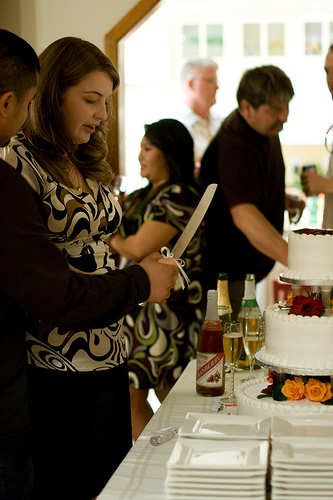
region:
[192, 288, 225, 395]
a bottle of red liquid with white top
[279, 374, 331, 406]
a set of yellow flowers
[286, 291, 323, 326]
a red flower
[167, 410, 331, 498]
stacks of small square plates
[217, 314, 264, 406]
a pair of champagne glasses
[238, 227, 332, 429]
a multi-layered cake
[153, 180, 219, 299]
a large cake knife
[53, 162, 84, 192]
a necklace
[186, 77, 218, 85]
a pair of corrective glasses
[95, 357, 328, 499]
a white tablecloth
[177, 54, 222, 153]
gray haired man in background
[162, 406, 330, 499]
stacks of white plates on table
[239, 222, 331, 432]
three tier white wedding cake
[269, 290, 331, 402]
decorative flowers on wedding cake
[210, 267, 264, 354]
two opened bottles of champagne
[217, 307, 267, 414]
several glasses of champagne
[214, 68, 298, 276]
mustached man in brown shirt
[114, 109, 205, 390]
woman wearing patterned dress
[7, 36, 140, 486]
woman wearing patterned top and black skirt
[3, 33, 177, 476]
man in long sleeve shirt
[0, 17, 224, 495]
man and woman about to cut into cake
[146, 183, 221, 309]
cake knife with a ribbon bow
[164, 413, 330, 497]
pile of white square plates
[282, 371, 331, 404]
two yellow roses on cake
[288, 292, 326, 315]
red flower on cake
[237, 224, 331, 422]
three tiered white cake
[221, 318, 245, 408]
filled champange glass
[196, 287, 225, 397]
unopened bottle of cranberry drink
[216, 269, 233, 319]
opened bottle of chanpange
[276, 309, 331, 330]
white frosting ruffle trim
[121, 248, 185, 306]
right hand of man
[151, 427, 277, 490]
stack of white plates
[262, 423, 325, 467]
top white plate on stack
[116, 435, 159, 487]
white table covering on table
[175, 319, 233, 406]
cover of wine bottle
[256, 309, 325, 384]
white frosting on cake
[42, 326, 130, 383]
design on someones shirt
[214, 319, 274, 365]
glasses filled with champagne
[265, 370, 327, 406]
flowers under the cake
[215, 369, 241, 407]
handle of wine glass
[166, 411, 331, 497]
four stacks of white plates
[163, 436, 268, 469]
white empty square plate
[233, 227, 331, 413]
white cake with flower decorations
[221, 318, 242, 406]
tall glass of yellow champagne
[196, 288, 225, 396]
closed bottle of cranberry flavored drink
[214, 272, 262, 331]
open champagne bottles on table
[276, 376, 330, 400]
beautiful yellow roses with green leaves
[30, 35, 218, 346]
woman is looking at drink list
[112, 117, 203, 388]
woman in dress drinking champagne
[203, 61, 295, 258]
man is drinking champagne